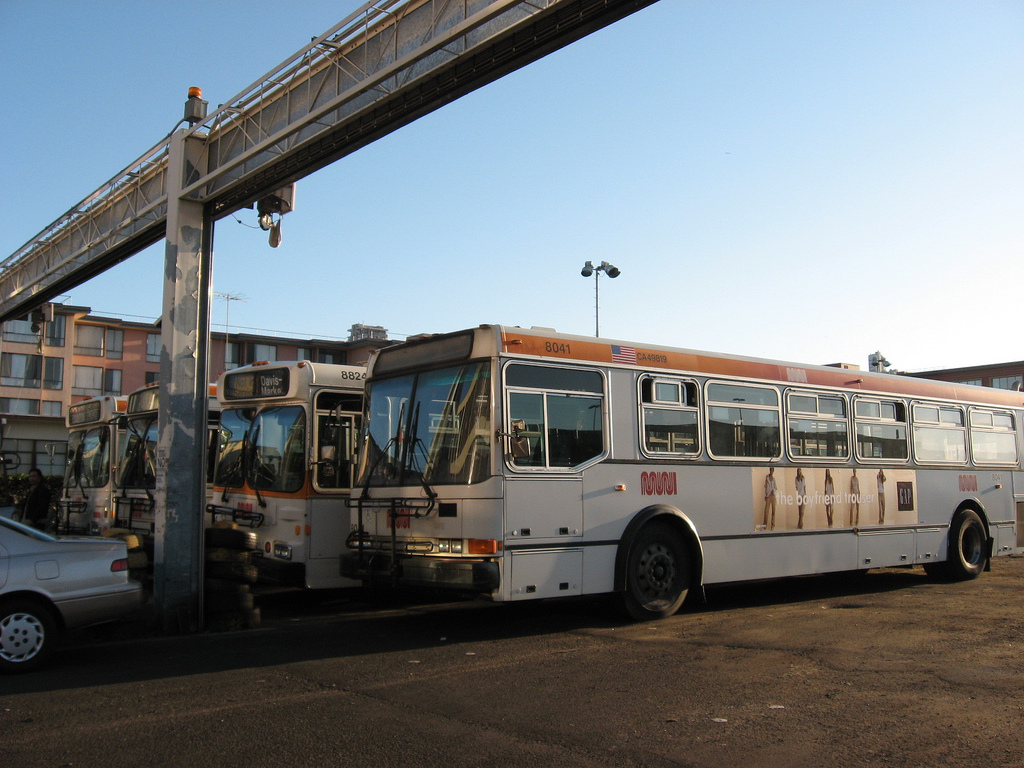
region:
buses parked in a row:
[232, 320, 1013, 606]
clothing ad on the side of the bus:
[754, 464, 923, 545]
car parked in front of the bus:
[9, 514, 150, 677]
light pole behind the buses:
[555, 244, 620, 334]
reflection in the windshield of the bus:
[357, 370, 485, 491]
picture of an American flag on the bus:
[606, 344, 641, 368]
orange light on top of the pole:
[180, 72, 204, 117]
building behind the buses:
[27, 309, 307, 385]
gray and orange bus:
[379, 339, 1022, 584]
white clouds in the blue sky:
[821, 259, 888, 298]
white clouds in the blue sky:
[600, 201, 665, 230]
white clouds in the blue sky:
[645, 153, 688, 182]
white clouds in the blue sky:
[688, 81, 797, 155]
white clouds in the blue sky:
[325, 219, 439, 270]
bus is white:
[361, 327, 1022, 599]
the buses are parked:
[52, 342, 1004, 603]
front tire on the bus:
[384, 329, 1017, 614]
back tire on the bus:
[378, 337, 1020, 604]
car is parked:
[5, 503, 133, 681]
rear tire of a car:
[4, 511, 141, 676]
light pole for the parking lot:
[567, 250, 626, 333]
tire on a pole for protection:
[209, 516, 270, 646]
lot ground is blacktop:
[7, 533, 1016, 755]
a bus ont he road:
[778, 408, 868, 498]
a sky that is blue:
[669, 16, 885, 165]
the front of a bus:
[318, 320, 546, 603]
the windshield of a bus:
[359, 382, 514, 490]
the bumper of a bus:
[362, 522, 481, 580]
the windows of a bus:
[494, 353, 1020, 481]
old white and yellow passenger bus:
[356, 315, 1020, 628]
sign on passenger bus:
[746, 470, 933, 531]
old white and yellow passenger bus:
[201, 350, 350, 575]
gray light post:
[561, 233, 628, 332]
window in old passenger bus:
[507, 368, 599, 463]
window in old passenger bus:
[356, 358, 470, 469]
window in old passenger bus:
[661, 379, 701, 457]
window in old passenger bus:
[693, 382, 786, 466]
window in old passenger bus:
[792, 405, 856, 451]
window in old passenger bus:
[868, 397, 903, 461]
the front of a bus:
[348, 353, 497, 595]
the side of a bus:
[503, 300, 976, 624]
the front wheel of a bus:
[634, 505, 748, 633]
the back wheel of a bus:
[886, 508, 1005, 584]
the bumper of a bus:
[351, 537, 485, 595]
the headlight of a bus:
[406, 516, 467, 556]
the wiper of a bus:
[356, 446, 443, 510]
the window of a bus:
[535, 370, 625, 463]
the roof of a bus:
[456, 306, 845, 411]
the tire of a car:
[2, 598, 75, 679]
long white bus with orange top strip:
[342, 325, 1022, 602]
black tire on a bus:
[619, 511, 697, 619]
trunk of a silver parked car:
[0, 502, 146, 670]